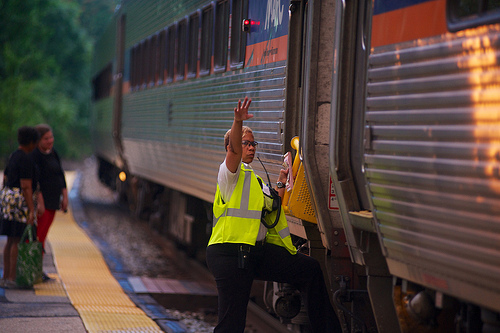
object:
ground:
[0, 189, 223, 333]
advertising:
[242, 0, 291, 69]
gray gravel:
[80, 157, 274, 333]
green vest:
[207, 162, 298, 255]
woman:
[30, 124, 68, 282]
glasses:
[242, 140, 258, 147]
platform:
[0, 169, 194, 333]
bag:
[15, 222, 42, 289]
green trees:
[0, 1, 109, 163]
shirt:
[31, 147, 67, 210]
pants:
[37, 209, 56, 255]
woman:
[204, 96, 343, 333]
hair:
[224, 125, 252, 152]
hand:
[234, 96, 254, 122]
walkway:
[126, 275, 274, 333]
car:
[90, 0, 500, 333]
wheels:
[127, 179, 210, 265]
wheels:
[263, 281, 310, 326]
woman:
[0, 126, 40, 290]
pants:
[206, 241, 343, 333]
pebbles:
[175, 305, 216, 333]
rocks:
[83, 169, 207, 281]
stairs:
[303, 119, 376, 333]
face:
[241, 132, 255, 164]